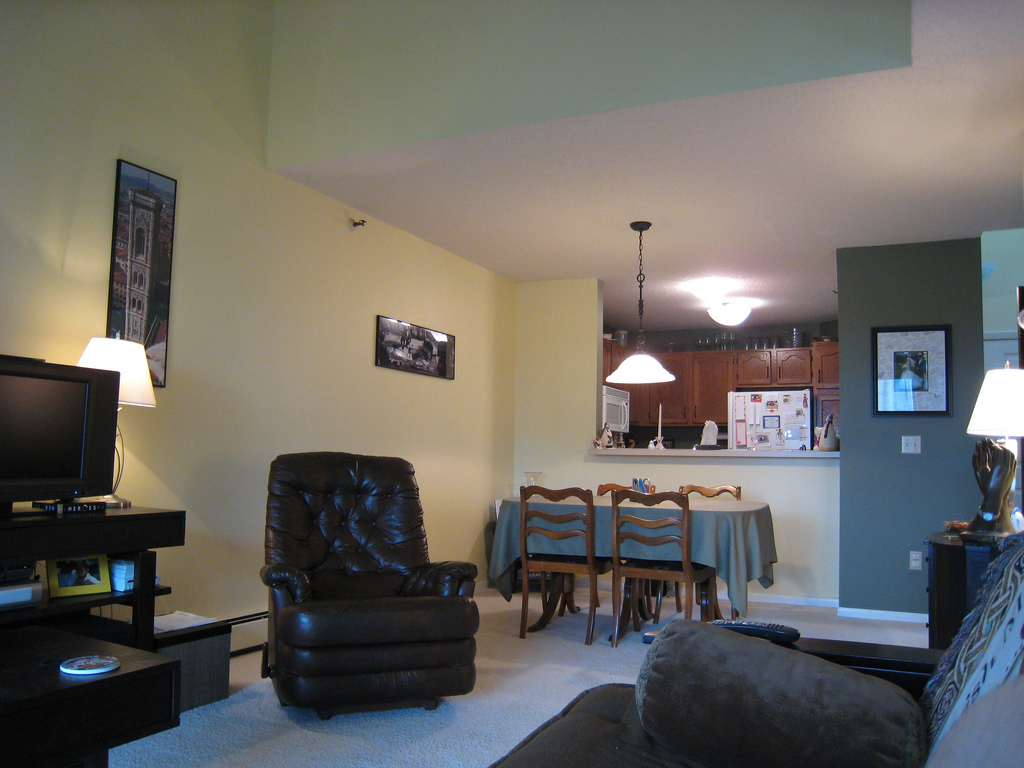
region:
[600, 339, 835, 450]
white refrigerator under brown wooden cabinets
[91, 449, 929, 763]
brown armchair on beige carpet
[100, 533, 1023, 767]
gray couch on beige carpet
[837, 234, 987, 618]
electrical outlet on green wall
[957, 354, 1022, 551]
hand sculpture next to white lamp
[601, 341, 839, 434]
white microwave next to cabinets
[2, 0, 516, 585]
framed picture on yellow wall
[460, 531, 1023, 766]
blanket draped on back of couch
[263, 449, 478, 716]
Brown leather recliner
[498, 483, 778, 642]
Four seat kitchen table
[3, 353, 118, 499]
television for watching movies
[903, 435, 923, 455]
switches to turn on and off the lights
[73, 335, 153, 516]
lamp for lighting the room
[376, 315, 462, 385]
black and white picture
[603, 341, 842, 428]
cupboards for storing food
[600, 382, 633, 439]
microwave for cooking food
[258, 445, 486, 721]
armchair is brown and leather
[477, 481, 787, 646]
brown wooden chairs next to table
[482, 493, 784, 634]
gray tablecloth covering the table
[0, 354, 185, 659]
TV is on top of TV stand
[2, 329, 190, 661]
white lamp is on top of TV stand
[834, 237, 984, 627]
framed picture hanging on green wall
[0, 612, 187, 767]
round coaster on coffee table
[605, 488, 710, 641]
brown chair is at a table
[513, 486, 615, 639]
brown chair is at a table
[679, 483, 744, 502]
brown chair is at a table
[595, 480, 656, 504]
brown chair is at a table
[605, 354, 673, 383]
round light is bright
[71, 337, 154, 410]
round light is bright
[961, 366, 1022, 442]
round light is bright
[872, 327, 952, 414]
picture has a black frame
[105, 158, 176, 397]
picture has a black frame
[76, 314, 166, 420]
lamp shade near the tv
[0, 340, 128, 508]
a tv in the room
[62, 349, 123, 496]
the side of the tv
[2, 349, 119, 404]
the top of the tv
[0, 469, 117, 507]
the bottom of the tv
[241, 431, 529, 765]
black leather chair in living room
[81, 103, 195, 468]
framed picture on wall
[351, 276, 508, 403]
framed picture on wall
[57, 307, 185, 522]
table lamp on stand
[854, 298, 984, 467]
framed picture on wall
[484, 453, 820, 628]
dining room table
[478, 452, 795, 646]
grey table cloth on dining room table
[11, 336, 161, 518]
flat screen tv on tv stand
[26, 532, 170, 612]
yellow framed picture on stand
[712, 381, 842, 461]
white fridge in kitchen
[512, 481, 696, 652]
two ladder back dining chairs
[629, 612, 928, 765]
tube shaped upholstered pillow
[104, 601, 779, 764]
room size white area rug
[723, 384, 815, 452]
refrigerator covered with posted items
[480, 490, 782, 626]
grey-blue fabric table cloth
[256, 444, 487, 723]
black leather recliner chair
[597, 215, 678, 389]
hanging dining area lamp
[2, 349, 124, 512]
flat screen television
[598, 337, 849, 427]
row of above counter kitchen cabinets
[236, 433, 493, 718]
black leather chair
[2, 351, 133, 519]
black flat screen tv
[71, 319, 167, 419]
white lamp shade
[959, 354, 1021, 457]
white lamp shade